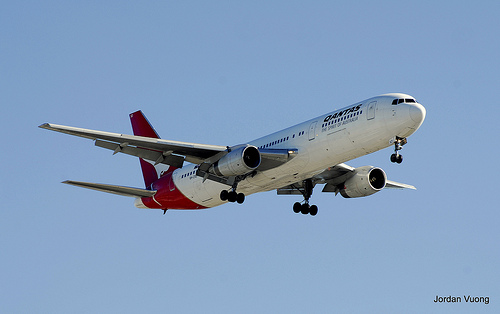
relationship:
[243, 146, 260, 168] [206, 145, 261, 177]
intake of engine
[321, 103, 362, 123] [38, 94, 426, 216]
logo on airplane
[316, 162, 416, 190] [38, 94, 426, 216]
right wing of airplane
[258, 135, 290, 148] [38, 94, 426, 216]
passenger windows on airplane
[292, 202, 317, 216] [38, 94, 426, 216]
wheels of airplane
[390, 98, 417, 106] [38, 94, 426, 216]
windshield of airplane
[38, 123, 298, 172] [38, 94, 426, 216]
left wing of airplane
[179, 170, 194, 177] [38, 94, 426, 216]
windows on airplane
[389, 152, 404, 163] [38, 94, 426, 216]
wheels on airplane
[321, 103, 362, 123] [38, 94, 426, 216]
logo on side of airplane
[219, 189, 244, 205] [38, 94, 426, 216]
wheels are underneath airplane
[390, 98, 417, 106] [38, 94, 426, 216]
windshield on front of airplane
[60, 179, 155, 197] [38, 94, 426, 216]
rear wing on airplane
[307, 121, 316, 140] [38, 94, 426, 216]
passenger door of airplane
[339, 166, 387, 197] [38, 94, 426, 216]
engine of airplane